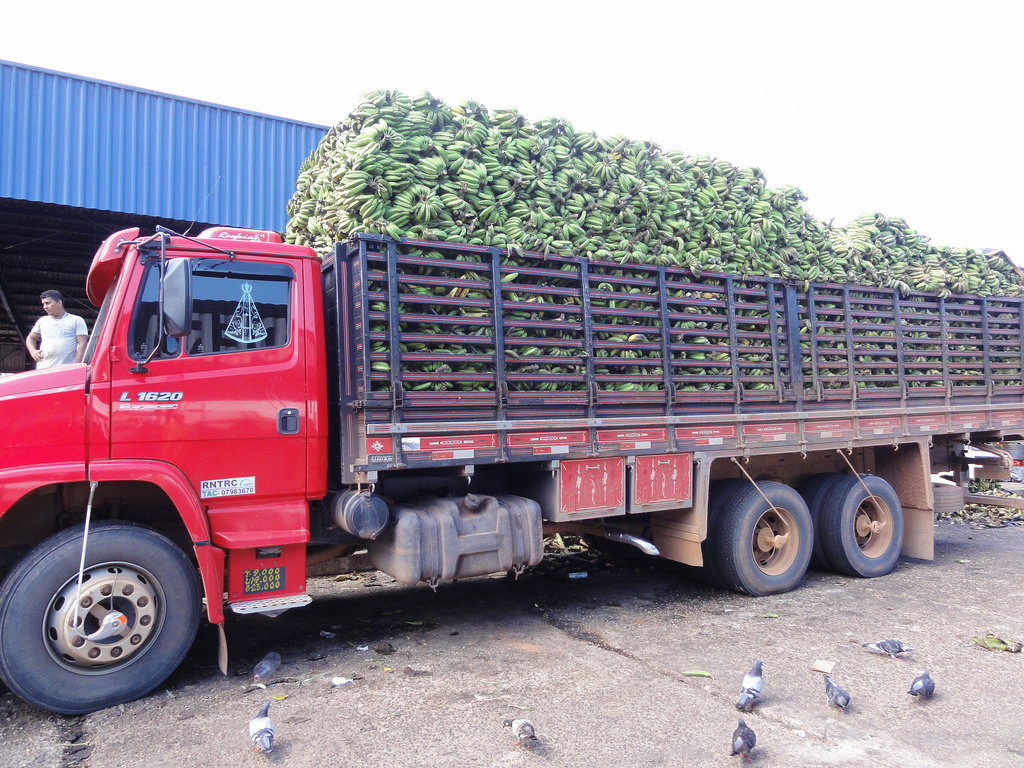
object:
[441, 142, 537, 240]
banana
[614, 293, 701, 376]
banana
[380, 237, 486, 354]
banana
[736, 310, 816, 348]
banana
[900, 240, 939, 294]
banana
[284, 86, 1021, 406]
banana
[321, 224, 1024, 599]
trailer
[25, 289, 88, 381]
man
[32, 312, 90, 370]
shirt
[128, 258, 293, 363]
window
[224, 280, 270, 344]
drawing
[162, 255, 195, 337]
mirror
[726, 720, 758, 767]
pigeon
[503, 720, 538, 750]
pigeon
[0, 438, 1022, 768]
ground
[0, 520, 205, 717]
tire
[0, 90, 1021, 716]
truck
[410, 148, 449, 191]
banana bunch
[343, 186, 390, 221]
banana bunch